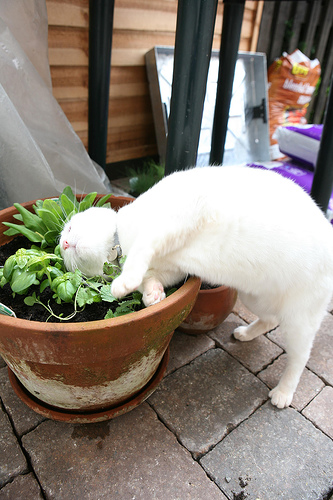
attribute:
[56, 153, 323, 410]
cat — white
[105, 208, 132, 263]
collar — gray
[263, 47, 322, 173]
bag — orange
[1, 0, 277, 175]
siding — wood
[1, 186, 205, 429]
pot — terra cotta, large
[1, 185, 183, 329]
plant — green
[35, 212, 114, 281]
head — white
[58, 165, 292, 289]
cat — white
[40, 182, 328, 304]
cat — standing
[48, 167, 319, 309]
cat — rubbing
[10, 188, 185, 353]
plants — green, growing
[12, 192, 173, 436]
pot — planting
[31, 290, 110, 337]
soil — black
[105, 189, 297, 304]
fur — white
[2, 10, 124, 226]
sheeting — transparent, plastic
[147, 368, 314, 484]
tile — stone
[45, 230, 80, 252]
nose — pink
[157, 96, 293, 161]
tray — SILVER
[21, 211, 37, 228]
leaf — green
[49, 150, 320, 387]
furry kitten — white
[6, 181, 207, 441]
cotta planter — dirty brown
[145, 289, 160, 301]
toes — pink